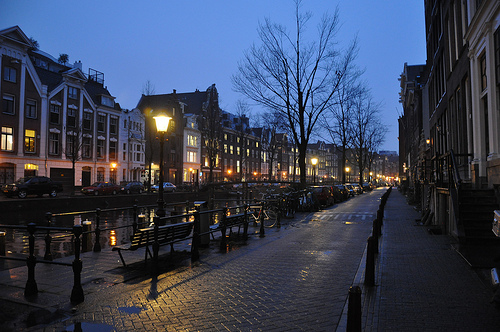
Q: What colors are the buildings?
A: White and brown.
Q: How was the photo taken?
A: With a telephoto lens.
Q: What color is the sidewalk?
A: Red.